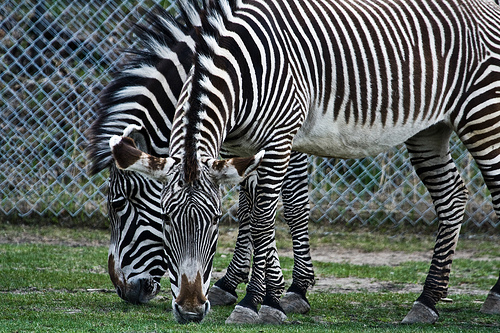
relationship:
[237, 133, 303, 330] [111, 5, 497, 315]
leg of a zebra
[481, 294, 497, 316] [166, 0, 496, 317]
hoof on zebra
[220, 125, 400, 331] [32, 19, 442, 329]
legs of zebra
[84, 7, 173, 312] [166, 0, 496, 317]
zebra next zebra